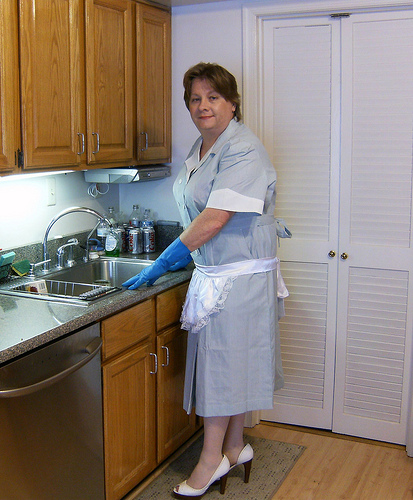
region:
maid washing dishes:
[1, 65, 280, 499]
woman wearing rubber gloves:
[116, 49, 299, 495]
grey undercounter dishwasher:
[3, 313, 98, 496]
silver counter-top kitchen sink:
[0, 201, 191, 306]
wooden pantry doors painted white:
[237, 5, 408, 452]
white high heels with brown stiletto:
[157, 441, 268, 496]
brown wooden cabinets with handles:
[3, 0, 171, 160]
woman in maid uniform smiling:
[118, 51, 289, 494]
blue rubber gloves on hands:
[119, 228, 200, 296]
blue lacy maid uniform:
[168, 118, 287, 415]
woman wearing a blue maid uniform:
[175, 124, 314, 363]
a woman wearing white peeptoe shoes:
[173, 454, 263, 491]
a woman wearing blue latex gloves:
[122, 243, 198, 294]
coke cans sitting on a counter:
[121, 225, 159, 257]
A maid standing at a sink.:
[132, 76, 283, 420]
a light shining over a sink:
[0, 162, 100, 186]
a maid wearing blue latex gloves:
[127, 235, 187, 308]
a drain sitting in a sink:
[12, 283, 101, 307]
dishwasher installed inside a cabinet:
[13, 338, 142, 497]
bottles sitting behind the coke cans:
[118, 203, 156, 240]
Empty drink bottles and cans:
[93, 202, 156, 258]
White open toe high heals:
[168, 440, 258, 499]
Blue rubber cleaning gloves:
[118, 234, 195, 292]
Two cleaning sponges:
[0, 247, 33, 282]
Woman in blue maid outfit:
[119, 59, 296, 499]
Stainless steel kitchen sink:
[0, 202, 170, 308]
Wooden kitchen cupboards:
[0, 0, 176, 180]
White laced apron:
[177, 254, 291, 336]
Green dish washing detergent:
[101, 216, 124, 259]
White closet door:
[238, 1, 412, 465]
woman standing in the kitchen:
[124, 61, 300, 498]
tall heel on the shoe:
[218, 471, 229, 496]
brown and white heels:
[162, 442, 256, 498]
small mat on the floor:
[133, 425, 306, 498]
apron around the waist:
[177, 253, 298, 335]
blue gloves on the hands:
[120, 238, 193, 295]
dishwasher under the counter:
[2, 315, 127, 497]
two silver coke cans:
[126, 226, 157, 257]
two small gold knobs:
[324, 247, 348, 258]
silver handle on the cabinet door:
[148, 352, 160, 378]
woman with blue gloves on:
[123, 232, 195, 282]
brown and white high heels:
[176, 450, 272, 487]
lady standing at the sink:
[82, 70, 273, 418]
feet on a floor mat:
[168, 443, 302, 499]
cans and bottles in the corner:
[125, 203, 160, 259]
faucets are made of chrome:
[29, 203, 121, 282]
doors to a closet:
[274, 3, 407, 450]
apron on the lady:
[169, 268, 287, 338]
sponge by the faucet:
[0, 252, 42, 297]